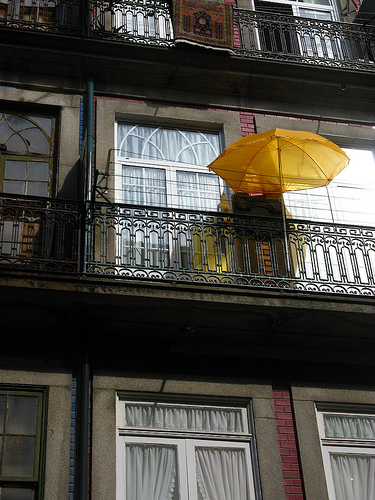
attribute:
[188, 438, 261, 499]
window — horizontal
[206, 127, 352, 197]
umbrella — open, yellow, large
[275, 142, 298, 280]
pole — long, blue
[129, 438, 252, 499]
curtain — white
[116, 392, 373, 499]
windows — multiple, rusted, framed, horizontal, small, glass, rectangular, curtained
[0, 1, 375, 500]
building — red, concrete, brick, blue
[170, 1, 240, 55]
rug — hanging, fringe, oriental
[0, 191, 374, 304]
railing — patterned, black, metal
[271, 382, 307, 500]
brick — red